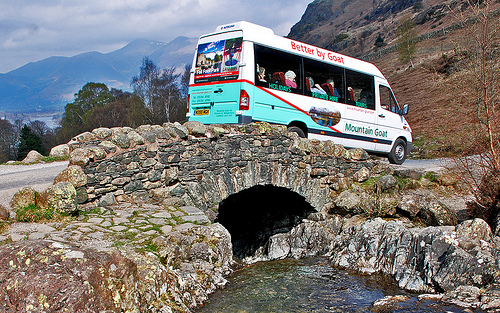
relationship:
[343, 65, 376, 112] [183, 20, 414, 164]
window on passenger van